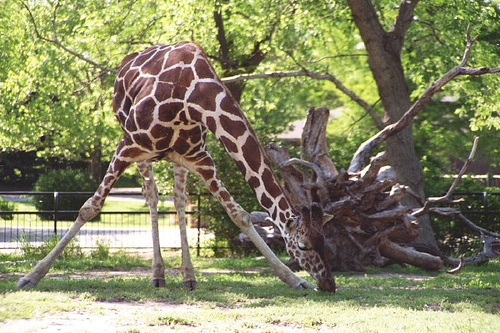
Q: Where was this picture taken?
A: The zoo.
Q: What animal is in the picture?
A: Giraffe.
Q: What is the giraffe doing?
A: Eating.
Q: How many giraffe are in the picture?
A: One.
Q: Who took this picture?
A: Zookeeper.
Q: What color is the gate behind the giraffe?
A: Black.